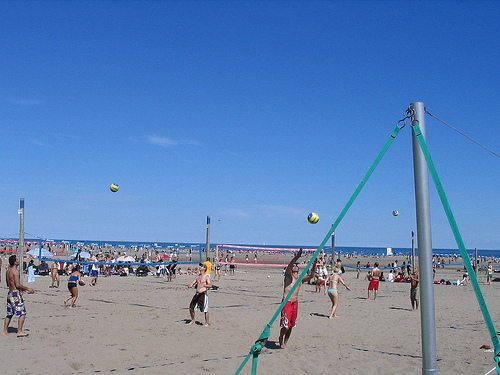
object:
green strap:
[234, 121, 403, 374]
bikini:
[66, 275, 80, 289]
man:
[184, 260, 214, 328]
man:
[366, 261, 382, 301]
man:
[407, 266, 422, 312]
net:
[214, 243, 327, 269]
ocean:
[0, 235, 500, 257]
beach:
[0, 242, 500, 374]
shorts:
[188, 289, 210, 314]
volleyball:
[108, 182, 122, 194]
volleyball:
[392, 208, 400, 217]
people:
[364, 262, 382, 301]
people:
[406, 270, 419, 313]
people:
[1, 253, 36, 338]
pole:
[407, 99, 438, 374]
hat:
[198, 261, 207, 270]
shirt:
[202, 259, 214, 275]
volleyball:
[305, 210, 322, 224]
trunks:
[4, 287, 28, 319]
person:
[62, 266, 87, 310]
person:
[280, 243, 306, 348]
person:
[323, 262, 352, 319]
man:
[201, 256, 211, 279]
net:
[22, 231, 204, 266]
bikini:
[324, 277, 341, 297]